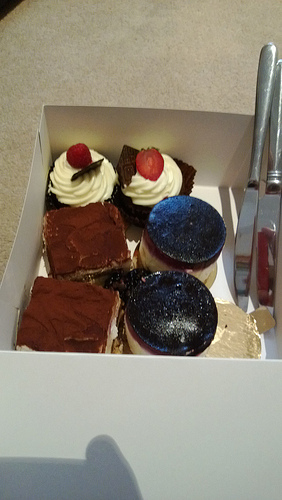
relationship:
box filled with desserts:
[0, 104, 281, 497] [15, 143, 275, 360]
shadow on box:
[0, 435, 141, 499] [0, 104, 281, 497]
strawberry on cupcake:
[133, 147, 165, 182] [115, 146, 197, 229]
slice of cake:
[41, 202, 133, 289] [41, 200, 133, 286]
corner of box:
[37, 104, 64, 160] [0, 104, 281, 497]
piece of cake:
[41, 202, 136, 286] [41, 200, 133, 286]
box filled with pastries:
[0, 104, 281, 497] [15, 143, 275, 360]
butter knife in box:
[255, 59, 281, 317] [0, 104, 281, 497]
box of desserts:
[0, 104, 281, 497] [15, 143, 275, 360]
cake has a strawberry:
[41, 200, 133, 286] [133, 147, 165, 182]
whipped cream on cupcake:
[117, 152, 183, 205] [115, 146, 197, 229]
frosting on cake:
[43, 202, 131, 277] [41, 200, 133, 286]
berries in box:
[106, 266, 153, 308] [0, 104, 281, 497]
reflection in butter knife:
[254, 228, 277, 309] [255, 59, 281, 317]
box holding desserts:
[0, 104, 281, 497] [15, 143, 275, 360]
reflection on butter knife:
[254, 228, 277, 309] [255, 59, 281, 317]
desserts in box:
[15, 143, 275, 360] [0, 104, 281, 497]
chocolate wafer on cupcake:
[115, 143, 139, 188] [115, 146, 197, 229]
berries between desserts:
[106, 266, 153, 308] [15, 143, 275, 360]